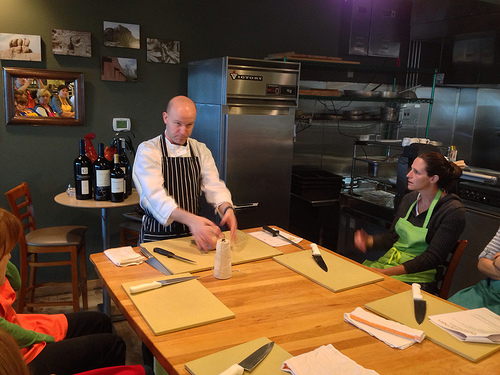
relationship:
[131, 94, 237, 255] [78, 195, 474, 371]
man at table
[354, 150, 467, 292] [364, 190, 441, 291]
person in apron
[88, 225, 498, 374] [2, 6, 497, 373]
table in room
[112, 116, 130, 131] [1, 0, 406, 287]
thermostat on wall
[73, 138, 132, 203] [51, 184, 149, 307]
bottles on table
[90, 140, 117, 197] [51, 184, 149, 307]
bottles on table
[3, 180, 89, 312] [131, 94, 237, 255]
chair to left of man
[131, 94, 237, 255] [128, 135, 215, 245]
man wearing apron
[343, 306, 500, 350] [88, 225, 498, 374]
papers on table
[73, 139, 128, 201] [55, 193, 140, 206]
wine on table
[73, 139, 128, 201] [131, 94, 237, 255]
wine behind man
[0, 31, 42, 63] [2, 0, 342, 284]
picture hanging on wall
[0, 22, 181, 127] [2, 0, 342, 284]
picture hanging on wall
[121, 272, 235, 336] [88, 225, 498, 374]
board on table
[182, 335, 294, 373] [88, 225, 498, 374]
cutting boards on table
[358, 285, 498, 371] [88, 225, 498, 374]
cutting boards on table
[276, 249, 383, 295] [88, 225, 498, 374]
cutting boards on table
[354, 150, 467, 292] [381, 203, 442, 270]
person wearing apron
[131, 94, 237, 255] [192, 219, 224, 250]
man handling meat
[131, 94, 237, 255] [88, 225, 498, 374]
man around table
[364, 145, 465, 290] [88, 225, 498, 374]
person around table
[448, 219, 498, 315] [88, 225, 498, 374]
person around table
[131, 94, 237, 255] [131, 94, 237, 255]
man watching man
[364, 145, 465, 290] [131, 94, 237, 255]
person watching man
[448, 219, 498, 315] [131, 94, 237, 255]
person watching man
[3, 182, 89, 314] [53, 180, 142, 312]
chair at table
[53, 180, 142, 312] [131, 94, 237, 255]
table behind man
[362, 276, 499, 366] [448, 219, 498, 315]
papers in front of person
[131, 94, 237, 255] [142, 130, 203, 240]
man wearing apron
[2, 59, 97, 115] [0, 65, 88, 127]
photo hanging in frame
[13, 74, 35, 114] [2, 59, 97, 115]
person shown in photo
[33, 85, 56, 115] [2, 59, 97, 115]
person shown in photo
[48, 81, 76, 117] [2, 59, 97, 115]
person shown in photo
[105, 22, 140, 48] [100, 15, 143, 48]
mountain shown in picture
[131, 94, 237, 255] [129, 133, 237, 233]
man wearing shirt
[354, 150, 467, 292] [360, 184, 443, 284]
person wearing apron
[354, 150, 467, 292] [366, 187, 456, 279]
person wearing apron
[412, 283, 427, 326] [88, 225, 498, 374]
butcher knife lying on top of table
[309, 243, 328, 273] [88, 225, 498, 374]
butcher knife lying on top of table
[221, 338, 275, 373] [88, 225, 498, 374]
knives lying on top of table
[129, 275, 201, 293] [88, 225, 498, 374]
butcher knife lying on top of table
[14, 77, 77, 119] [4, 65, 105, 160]
photo hanging in frame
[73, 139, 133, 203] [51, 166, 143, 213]
wine bottle sitting on top of table top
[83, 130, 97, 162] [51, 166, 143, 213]
wine bottle sitting on top of table top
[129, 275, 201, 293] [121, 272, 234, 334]
butcher knife lying on top of board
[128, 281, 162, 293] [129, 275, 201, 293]
handle belonging to butcher knife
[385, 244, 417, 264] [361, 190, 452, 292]
tie wrapped around apron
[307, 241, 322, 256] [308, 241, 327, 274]
handle belonging to butcher knife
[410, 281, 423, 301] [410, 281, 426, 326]
handle belonging to butcher knife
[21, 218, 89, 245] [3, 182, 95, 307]
seat covering chair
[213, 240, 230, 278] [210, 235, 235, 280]
white string wrapped around spindle